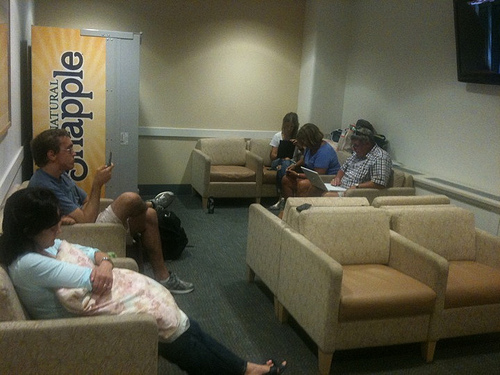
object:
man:
[27, 125, 198, 298]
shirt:
[26, 164, 87, 222]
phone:
[104, 151, 119, 171]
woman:
[0, 182, 292, 374]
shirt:
[6, 239, 106, 322]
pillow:
[55, 237, 193, 344]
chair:
[279, 203, 444, 374]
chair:
[384, 206, 499, 362]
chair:
[241, 194, 373, 321]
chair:
[189, 135, 262, 215]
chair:
[368, 191, 452, 207]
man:
[315, 116, 396, 204]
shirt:
[332, 142, 395, 200]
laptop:
[294, 162, 349, 197]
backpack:
[135, 198, 189, 262]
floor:
[134, 174, 499, 374]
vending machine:
[30, 26, 143, 205]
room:
[0, 0, 499, 373]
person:
[263, 112, 304, 211]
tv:
[452, 1, 500, 89]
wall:
[340, 0, 497, 206]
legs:
[93, 188, 159, 233]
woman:
[277, 120, 341, 216]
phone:
[283, 164, 298, 183]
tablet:
[275, 135, 297, 165]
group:
[239, 192, 499, 374]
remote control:
[296, 200, 312, 217]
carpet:
[1, 193, 500, 374]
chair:
[245, 134, 293, 207]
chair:
[16, 180, 137, 260]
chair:
[0, 250, 160, 373]